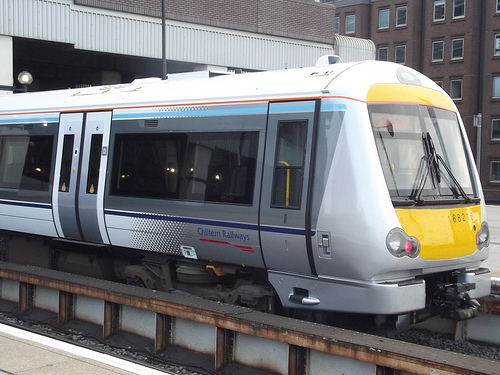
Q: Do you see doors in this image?
A: Yes, there is a door.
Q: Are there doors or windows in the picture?
A: Yes, there is a door.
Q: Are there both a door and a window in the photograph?
A: Yes, there are both a door and a window.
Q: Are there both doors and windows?
A: Yes, there are both a door and a window.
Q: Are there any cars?
A: No, there are no cars.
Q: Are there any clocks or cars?
A: No, there are no cars or clocks.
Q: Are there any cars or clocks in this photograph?
A: No, there are no cars or clocks.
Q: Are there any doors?
A: Yes, there is a door.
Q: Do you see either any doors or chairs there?
A: Yes, there is a door.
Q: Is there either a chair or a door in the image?
A: Yes, there is a door.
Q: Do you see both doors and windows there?
A: Yes, there are both a door and a window.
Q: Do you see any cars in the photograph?
A: No, there are no cars.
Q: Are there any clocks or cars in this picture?
A: No, there are no cars or clocks.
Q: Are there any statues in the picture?
A: No, there are no statues.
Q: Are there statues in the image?
A: No, there are no statues.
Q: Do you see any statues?
A: No, there are no statues.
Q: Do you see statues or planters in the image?
A: No, there are no statues or planters.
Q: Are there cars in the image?
A: No, there are no cars.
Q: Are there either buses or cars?
A: No, there are no cars or buses.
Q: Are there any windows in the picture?
A: Yes, there is a window.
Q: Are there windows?
A: Yes, there is a window.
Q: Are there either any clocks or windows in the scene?
A: Yes, there is a window.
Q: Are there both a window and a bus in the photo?
A: No, there is a window but no buses.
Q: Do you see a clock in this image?
A: No, there are no clocks.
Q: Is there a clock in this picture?
A: No, there are no clocks.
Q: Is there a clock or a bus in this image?
A: No, there are no clocks or buses.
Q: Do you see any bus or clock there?
A: No, there are no clocks or buses.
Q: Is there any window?
A: Yes, there is a window.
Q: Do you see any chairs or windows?
A: Yes, there is a window.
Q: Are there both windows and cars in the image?
A: No, there is a window but no cars.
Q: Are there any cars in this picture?
A: No, there are no cars.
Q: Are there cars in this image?
A: No, there are no cars.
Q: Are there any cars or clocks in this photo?
A: No, there are no cars or clocks.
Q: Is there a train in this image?
A: Yes, there is a train.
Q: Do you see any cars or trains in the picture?
A: Yes, there is a train.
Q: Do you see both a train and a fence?
A: No, there is a train but no fences.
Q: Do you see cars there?
A: No, there are no cars.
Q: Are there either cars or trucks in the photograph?
A: No, there are no cars or trucks.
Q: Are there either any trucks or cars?
A: No, there are no cars or trucks.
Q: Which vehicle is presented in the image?
A: The vehicle is a train.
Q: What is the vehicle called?
A: The vehicle is a train.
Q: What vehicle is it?
A: The vehicle is a train.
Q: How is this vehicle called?
A: This is a train.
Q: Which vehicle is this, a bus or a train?
A: This is a train.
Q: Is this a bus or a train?
A: This is a train.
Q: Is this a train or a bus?
A: This is a train.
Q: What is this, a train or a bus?
A: This is a train.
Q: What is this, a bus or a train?
A: This is a train.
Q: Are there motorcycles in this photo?
A: No, there are no motorcycles.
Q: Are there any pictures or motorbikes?
A: No, there are no motorbikes or pictures.